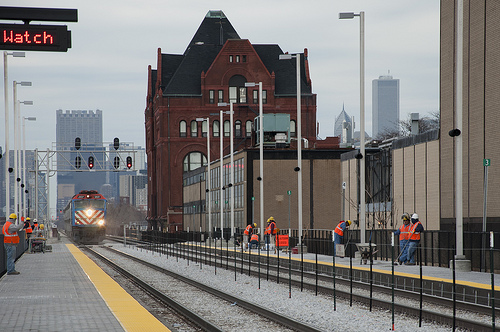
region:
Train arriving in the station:
[57, 183, 115, 242]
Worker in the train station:
[400, 208, 422, 258]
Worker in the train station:
[327, 210, 355, 247]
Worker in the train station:
[240, 216, 264, 248]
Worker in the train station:
[24, 211, 40, 240]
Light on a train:
[85, 204, 94, 218]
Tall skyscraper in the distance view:
[366, 65, 408, 156]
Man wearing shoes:
[5, 267, 24, 276]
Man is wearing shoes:
[2, 267, 22, 275]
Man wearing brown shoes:
[5, 265, 25, 277]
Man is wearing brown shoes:
[3, 267, 23, 277]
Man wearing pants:
[0, 238, 22, 273]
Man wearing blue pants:
[0, 242, 17, 273]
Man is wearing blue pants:
[3, 238, 20, 272]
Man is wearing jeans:
[5, 236, 16, 275]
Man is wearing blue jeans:
[5, 239, 17, 274]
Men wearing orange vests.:
[390, 208, 425, 265]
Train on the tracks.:
[55, 183, 110, 251]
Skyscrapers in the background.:
[369, 64, 407, 141]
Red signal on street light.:
[82, 150, 99, 170]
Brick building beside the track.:
[132, 3, 342, 237]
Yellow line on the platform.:
[59, 235, 167, 330]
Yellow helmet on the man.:
[3, 205, 23, 230]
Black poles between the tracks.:
[127, 217, 499, 330]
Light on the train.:
[80, 203, 97, 220]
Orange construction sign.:
[270, 228, 292, 248]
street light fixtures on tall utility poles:
[197, 1, 492, 266]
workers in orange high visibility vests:
[240, 211, 425, 261]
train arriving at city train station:
[70, 191, 105, 241]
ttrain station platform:
[3, 225, 161, 327]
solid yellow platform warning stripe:
[62, 240, 172, 327]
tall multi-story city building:
[141, 10, 316, 229]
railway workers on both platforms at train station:
[3, 210, 424, 276]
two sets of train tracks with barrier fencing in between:
[78, 228, 495, 328]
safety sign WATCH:
[0, 21, 72, 52]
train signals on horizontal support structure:
[31, 137, 136, 173]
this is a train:
[63, 183, 106, 244]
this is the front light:
[85, 205, 93, 215]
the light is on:
[84, 207, 94, 219]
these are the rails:
[121, 255, 166, 289]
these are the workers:
[391, 206, 430, 259]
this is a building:
[157, 35, 298, 151]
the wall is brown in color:
[176, 95, 192, 115]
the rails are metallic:
[174, 287, 264, 325]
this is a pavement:
[32, 275, 87, 322]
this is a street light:
[324, 6, 369, 25]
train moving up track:
[65, 187, 111, 250]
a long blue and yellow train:
[55, 184, 106, 246]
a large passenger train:
[62, 191, 104, 243]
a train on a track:
[52, 188, 107, 246]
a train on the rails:
[55, 184, 109, 248]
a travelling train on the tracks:
[55, 184, 109, 252]